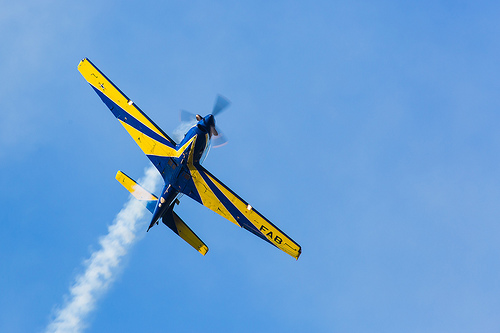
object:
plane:
[74, 56, 302, 261]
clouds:
[0, 0, 499, 332]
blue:
[162, 213, 172, 222]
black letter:
[265, 231, 273, 239]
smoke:
[41, 164, 168, 332]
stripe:
[161, 206, 179, 235]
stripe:
[187, 145, 241, 228]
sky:
[1, 0, 499, 332]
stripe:
[193, 135, 275, 244]